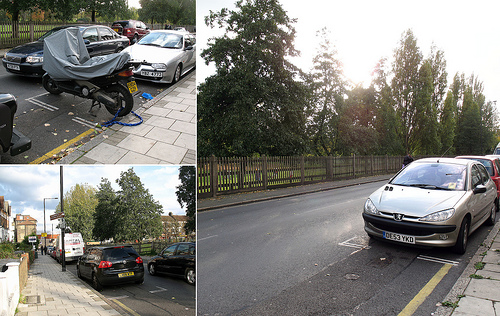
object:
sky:
[198, 0, 498, 128]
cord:
[96, 107, 143, 128]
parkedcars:
[148, 242, 196, 284]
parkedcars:
[56, 232, 85, 264]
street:
[202, 164, 468, 314]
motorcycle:
[42, 25, 139, 117]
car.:
[119, 30, 196, 83]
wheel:
[148, 262, 156, 276]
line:
[399, 263, 453, 313]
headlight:
[419, 208, 455, 223]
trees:
[204, 9, 499, 149]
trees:
[62, 167, 195, 238]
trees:
[5, 0, 195, 32]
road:
[5, 20, 190, 132]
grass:
[194, 160, 376, 196]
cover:
[42, 24, 130, 81]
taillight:
[135, 257, 143, 264]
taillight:
[98, 261, 112, 269]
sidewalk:
[57, 72, 195, 164]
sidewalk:
[430, 224, 498, 316]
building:
[13, 214, 38, 243]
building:
[1, 199, 12, 235]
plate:
[127, 81, 138, 94]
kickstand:
[87, 99, 101, 113]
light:
[55, 198, 59, 200]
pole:
[44, 198, 59, 234]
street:
[9, 47, 166, 145]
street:
[55, 250, 195, 315]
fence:
[196, 153, 403, 199]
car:
[453, 155, 500, 198]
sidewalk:
[9, 239, 130, 313]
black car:
[1, 23, 130, 77]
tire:
[104, 84, 134, 117]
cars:
[76, 245, 144, 291]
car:
[356, 153, 485, 250]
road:
[199, 174, 497, 313]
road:
[69, 255, 189, 313]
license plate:
[383, 230, 416, 244]